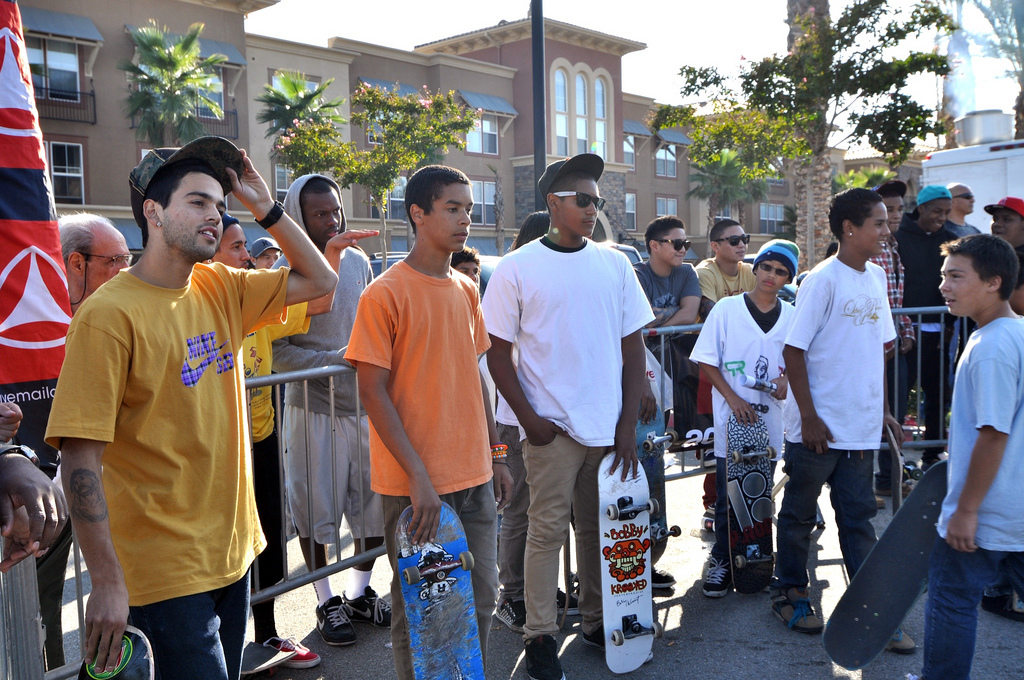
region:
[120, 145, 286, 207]
Boy wearing hat on head.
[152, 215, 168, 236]
Diamond earring in boy's ear.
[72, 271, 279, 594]
Boy wearing yellow shirt.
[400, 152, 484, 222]
Boy has short dark hair.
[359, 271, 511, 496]
Boy wearing orange shirt.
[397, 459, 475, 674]
Boy holding skateboard in hand.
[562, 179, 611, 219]
Sunglasses on man's face.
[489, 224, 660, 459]
Man wearing white shirt.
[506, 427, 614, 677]
Man wearing khaki pants.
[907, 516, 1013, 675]
Person wearing blue jeans.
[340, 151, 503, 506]
A young man wearing an orange shirt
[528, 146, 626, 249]
A boy wearing sunglasses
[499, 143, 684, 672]
A guy holding a skateboard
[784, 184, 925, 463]
a boy wearing a white T-shirt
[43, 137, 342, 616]
a guy wearing a yellow T-shirt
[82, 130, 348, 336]
a guy touching his hat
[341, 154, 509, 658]
A guy holding a blue skateboard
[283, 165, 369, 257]
a guy wearing a hoodie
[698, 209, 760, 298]
a boy wearing sunglasses and a yellow T-shirt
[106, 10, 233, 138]
A palm tree in front of the window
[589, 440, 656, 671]
white skateboard with design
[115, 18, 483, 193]
trees behind the crows of people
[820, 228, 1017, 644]
boy is carrying a skateboard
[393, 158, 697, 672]
two boys holding skateboards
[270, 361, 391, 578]
metal guard railing behind the boys with skateboards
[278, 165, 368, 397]
guy is wearing a grey hoodie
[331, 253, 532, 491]
boy is wearing an orange shirt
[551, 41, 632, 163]
arched windows in the building behind the people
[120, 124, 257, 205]
boy is adjusting his hat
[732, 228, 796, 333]
boy is wearing a blue beanie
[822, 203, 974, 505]
A person eating a orange.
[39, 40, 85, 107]
a window on a building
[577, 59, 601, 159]
a window on a building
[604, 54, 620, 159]
a window on a building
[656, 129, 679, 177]
a window on a building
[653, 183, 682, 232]
a window on a building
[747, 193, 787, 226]
a window on a building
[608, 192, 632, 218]
a window on a building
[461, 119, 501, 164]
a window on a building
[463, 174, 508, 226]
a window on a building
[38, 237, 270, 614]
Yellow shirt on a man.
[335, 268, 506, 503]
Orange shirt on a boy.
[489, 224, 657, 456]
White shirt on a boy.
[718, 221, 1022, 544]
Boys standing with skateboards.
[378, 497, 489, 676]
Blue skateboar in a hand.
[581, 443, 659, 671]
White and orange skateboard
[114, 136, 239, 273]
Hat on a man.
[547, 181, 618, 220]
Sunglasses on a man.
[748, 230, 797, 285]
Winter hat on a man.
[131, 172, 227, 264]
head of a man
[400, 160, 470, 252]
head of a man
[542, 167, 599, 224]
head of a man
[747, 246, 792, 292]
head of a man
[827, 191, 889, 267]
head of a man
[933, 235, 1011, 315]
head of a man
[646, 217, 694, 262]
head of a man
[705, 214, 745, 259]
head of a man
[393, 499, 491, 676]
skate board is blue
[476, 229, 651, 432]
the shirt is white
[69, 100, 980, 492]
many people on the street